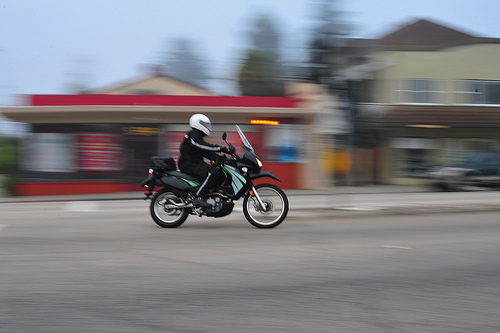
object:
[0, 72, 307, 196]
building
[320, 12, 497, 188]
building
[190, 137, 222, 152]
stripe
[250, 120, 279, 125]
lights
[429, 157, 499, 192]
blurryvehicle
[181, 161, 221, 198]
pants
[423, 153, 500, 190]
parked car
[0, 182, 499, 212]
side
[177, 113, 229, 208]
man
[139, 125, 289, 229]
bike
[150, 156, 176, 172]
pack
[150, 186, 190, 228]
tire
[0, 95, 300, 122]
red roof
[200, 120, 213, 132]
reflectors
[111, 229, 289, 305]
ground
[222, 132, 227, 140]
sideview mirror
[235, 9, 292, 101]
tree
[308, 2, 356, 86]
tree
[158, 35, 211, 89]
tree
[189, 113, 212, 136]
helmet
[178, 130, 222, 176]
jacket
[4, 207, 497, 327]
road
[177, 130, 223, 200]
clothing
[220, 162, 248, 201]
trim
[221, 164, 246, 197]
designs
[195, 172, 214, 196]
reflector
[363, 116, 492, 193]
background